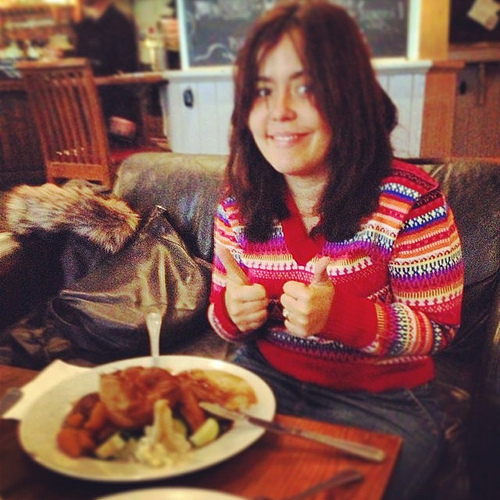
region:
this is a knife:
[200, 399, 383, 467]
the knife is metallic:
[206, 400, 382, 463]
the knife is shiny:
[204, 402, 217, 409]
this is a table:
[256, 446, 305, 488]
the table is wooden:
[253, 450, 289, 489]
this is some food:
[50, 368, 233, 446]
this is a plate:
[28, 409, 56, 456]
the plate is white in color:
[30, 404, 51, 444]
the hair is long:
[310, 35, 390, 241]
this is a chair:
[13, 58, 126, 169]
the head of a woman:
[218, 5, 383, 180]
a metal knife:
[197, 399, 389, 469]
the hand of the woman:
[277, 247, 349, 342]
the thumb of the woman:
[311, 251, 331, 284]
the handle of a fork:
[140, 305, 170, 371]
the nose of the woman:
[267, 75, 303, 125]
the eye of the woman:
[252, 79, 274, 102]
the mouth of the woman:
[258, 130, 310, 145]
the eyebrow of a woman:
[253, 70, 275, 85]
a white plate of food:
[15, 344, 282, 482]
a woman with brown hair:
[168, 27, 387, 234]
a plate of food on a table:
[2, 365, 276, 487]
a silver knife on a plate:
[178, 394, 378, 458]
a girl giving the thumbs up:
[138, 61, 370, 362]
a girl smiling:
[212, 35, 334, 206]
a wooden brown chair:
[21, 71, 124, 193]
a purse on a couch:
[33, 212, 223, 375]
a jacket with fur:
[0, 162, 157, 267]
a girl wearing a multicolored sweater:
[206, 72, 439, 369]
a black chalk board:
[151, 2, 441, 74]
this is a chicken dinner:
[46, 349, 276, 465]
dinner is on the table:
[27, 330, 354, 486]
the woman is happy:
[225, 12, 393, 237]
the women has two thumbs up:
[203, 19, 465, 399]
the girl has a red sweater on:
[197, 11, 472, 386]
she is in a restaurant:
[16, 17, 476, 497]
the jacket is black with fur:
[20, 179, 237, 359]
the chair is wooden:
[18, 57, 128, 185]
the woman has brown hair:
[214, 4, 411, 236]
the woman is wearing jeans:
[198, 3, 474, 473]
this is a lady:
[218, 10, 449, 394]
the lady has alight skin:
[276, 132, 316, 163]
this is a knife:
[266, 417, 368, 457]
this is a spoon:
[142, 305, 167, 355]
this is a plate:
[215, 435, 252, 452]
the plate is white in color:
[223, 444, 239, 451]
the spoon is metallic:
[148, 311, 158, 331]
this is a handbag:
[115, 239, 192, 297]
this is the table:
[259, 447, 290, 493]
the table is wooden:
[257, 450, 278, 461]